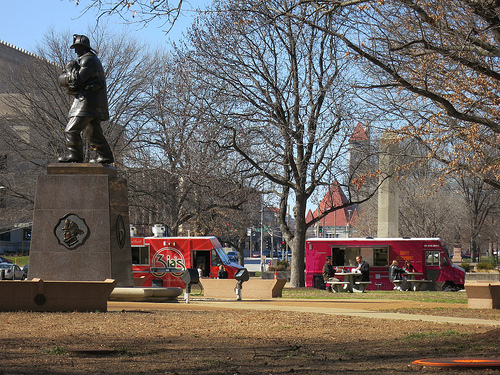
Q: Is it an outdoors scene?
A: Yes, it is outdoors.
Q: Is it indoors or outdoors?
A: It is outdoors.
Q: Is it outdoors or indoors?
A: It is outdoors.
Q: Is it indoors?
A: No, it is outdoors.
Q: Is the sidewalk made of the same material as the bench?
A: Yes, both the sidewalk and the bench are made of cement.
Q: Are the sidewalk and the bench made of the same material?
A: Yes, both the sidewalk and the bench are made of cement.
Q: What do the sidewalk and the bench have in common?
A: The material, both the sidewalk and the bench are concrete.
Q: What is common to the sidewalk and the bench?
A: The material, both the sidewalk and the bench are concrete.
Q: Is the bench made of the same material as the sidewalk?
A: Yes, both the bench and the sidewalk are made of cement.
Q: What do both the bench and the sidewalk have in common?
A: The material, both the bench and the sidewalk are concrete.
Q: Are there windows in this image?
A: Yes, there is a window.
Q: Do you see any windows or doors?
A: Yes, there is a window.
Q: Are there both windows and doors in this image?
A: No, there is a window but no doors.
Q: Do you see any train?
A: No, there are no trains.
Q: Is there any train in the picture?
A: No, there are no trains.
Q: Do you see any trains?
A: No, there are no trains.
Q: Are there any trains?
A: No, there are no trains.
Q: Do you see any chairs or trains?
A: No, there are no trains or chairs.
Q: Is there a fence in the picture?
A: No, there are no fences.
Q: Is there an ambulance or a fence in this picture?
A: No, there are no fences or ambulances.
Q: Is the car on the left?
A: Yes, the car is on the left of the image.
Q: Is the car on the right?
A: No, the car is on the left of the image.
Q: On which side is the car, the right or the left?
A: The car is on the left of the image.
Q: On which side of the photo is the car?
A: The car is on the left of the image.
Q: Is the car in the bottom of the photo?
A: Yes, the car is in the bottom of the image.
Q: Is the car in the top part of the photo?
A: No, the car is in the bottom of the image.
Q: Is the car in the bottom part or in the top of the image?
A: The car is in the bottom of the image.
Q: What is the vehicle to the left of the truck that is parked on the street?
A: The vehicle is a car.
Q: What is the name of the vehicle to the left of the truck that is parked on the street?
A: The vehicle is a car.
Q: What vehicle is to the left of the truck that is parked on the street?
A: The vehicle is a car.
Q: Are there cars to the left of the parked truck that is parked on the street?
A: Yes, there is a car to the left of the truck.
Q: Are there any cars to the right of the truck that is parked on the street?
A: No, the car is to the left of the truck.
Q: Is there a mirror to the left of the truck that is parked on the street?
A: No, there is a car to the left of the truck.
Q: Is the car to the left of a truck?
A: Yes, the car is to the left of a truck.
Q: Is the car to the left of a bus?
A: No, the car is to the left of a truck.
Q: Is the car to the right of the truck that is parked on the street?
A: No, the car is to the left of the truck.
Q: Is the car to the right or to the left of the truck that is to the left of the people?
A: The car is to the left of the truck.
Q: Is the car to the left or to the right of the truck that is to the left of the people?
A: The car is to the left of the truck.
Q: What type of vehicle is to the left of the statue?
A: The vehicle is a car.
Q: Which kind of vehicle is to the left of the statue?
A: The vehicle is a car.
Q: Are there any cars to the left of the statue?
A: Yes, there is a car to the left of the statue.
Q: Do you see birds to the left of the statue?
A: No, there is a car to the left of the statue.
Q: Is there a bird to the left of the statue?
A: No, there is a car to the left of the statue.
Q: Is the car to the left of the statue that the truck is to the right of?
A: Yes, the car is to the left of the statue.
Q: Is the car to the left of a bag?
A: No, the car is to the left of the statue.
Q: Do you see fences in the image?
A: No, there are no fences.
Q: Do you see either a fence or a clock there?
A: No, there are no fences or clocks.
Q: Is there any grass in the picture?
A: Yes, there is grass.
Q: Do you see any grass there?
A: Yes, there is grass.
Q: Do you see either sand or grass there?
A: Yes, there is grass.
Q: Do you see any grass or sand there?
A: Yes, there is grass.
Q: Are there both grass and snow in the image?
A: No, there is grass but no snow.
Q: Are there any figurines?
A: No, there are no figurines.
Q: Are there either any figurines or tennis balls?
A: No, there are no figurines or tennis balls.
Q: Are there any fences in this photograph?
A: No, there are no fences.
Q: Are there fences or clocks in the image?
A: No, there are no fences or clocks.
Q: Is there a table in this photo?
A: Yes, there is a table.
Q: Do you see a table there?
A: Yes, there is a table.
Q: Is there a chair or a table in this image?
A: Yes, there is a table.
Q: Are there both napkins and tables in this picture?
A: No, there is a table but no napkins.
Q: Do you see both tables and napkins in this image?
A: No, there is a table but no napkins.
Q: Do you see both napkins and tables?
A: No, there is a table but no napkins.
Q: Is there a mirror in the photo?
A: No, there are no mirrors.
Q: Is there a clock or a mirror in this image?
A: No, there are no mirrors or clocks.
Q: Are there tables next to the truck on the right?
A: Yes, there is a table next to the truck.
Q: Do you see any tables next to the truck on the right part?
A: Yes, there is a table next to the truck.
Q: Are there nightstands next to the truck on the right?
A: No, there is a table next to the truck.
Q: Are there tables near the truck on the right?
A: Yes, there is a table near the truck.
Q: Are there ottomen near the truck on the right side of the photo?
A: No, there is a table near the truck.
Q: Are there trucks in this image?
A: Yes, there is a truck.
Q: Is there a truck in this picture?
A: Yes, there is a truck.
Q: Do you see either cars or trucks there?
A: Yes, there is a truck.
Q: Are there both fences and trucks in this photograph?
A: No, there is a truck but no fences.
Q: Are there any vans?
A: No, there are no vans.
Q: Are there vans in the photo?
A: No, there are no vans.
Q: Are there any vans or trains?
A: No, there are no vans or trains.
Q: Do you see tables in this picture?
A: Yes, there is a table.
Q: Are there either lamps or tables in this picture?
A: Yes, there is a table.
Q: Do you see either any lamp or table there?
A: Yes, there is a table.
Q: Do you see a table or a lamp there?
A: Yes, there is a table.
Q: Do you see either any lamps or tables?
A: Yes, there is a table.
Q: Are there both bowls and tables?
A: No, there is a table but no bowls.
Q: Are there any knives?
A: No, there are no knives.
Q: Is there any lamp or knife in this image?
A: No, there are no knives or lamps.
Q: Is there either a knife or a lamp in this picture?
A: No, there are no knives or lamps.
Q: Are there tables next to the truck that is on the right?
A: Yes, there is a table next to the truck.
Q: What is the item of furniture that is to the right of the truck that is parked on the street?
A: The piece of furniture is a table.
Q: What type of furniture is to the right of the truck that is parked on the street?
A: The piece of furniture is a table.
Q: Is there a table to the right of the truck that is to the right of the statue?
A: Yes, there is a table to the right of the truck.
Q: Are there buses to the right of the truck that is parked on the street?
A: No, there is a table to the right of the truck.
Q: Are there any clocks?
A: No, there are no clocks.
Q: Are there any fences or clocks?
A: No, there are no clocks or fences.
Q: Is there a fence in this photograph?
A: No, there are no fences.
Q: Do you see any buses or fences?
A: No, there are no fences or buses.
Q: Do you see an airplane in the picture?
A: No, there are no airplanes.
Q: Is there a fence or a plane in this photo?
A: No, there are no airplanes or fences.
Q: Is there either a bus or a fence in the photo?
A: No, there are no fences or buses.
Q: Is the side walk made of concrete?
A: Yes, the side walk is made of concrete.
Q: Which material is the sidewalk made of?
A: The sidewalk is made of cement.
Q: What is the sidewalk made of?
A: The sidewalk is made of concrete.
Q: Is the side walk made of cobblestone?
A: No, the side walk is made of concrete.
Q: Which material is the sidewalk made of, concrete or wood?
A: The sidewalk is made of concrete.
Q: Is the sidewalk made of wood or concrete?
A: The sidewalk is made of concrete.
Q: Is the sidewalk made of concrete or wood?
A: The sidewalk is made of concrete.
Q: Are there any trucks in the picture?
A: Yes, there is a truck.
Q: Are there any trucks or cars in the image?
A: Yes, there is a truck.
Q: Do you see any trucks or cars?
A: Yes, there is a truck.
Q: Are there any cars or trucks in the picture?
A: Yes, there is a truck.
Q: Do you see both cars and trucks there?
A: Yes, there are both a truck and a car.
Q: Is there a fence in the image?
A: No, there are no fences.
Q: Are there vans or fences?
A: No, there are no fences or vans.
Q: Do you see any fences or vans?
A: No, there are no fences or vans.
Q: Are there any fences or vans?
A: No, there are no fences or vans.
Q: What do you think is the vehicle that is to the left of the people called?
A: The vehicle is a truck.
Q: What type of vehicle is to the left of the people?
A: The vehicle is a truck.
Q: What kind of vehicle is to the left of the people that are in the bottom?
A: The vehicle is a truck.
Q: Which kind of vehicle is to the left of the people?
A: The vehicle is a truck.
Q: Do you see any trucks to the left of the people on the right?
A: Yes, there is a truck to the left of the people.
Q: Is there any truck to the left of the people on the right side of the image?
A: Yes, there is a truck to the left of the people.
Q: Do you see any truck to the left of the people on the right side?
A: Yes, there is a truck to the left of the people.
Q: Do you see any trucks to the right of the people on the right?
A: No, the truck is to the left of the people.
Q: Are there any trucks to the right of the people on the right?
A: No, the truck is to the left of the people.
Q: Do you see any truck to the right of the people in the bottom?
A: No, the truck is to the left of the people.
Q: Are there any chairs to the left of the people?
A: No, there is a truck to the left of the people.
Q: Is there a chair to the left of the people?
A: No, there is a truck to the left of the people.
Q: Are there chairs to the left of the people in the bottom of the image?
A: No, there is a truck to the left of the people.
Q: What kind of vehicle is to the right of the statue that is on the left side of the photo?
A: The vehicle is a truck.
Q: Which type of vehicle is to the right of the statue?
A: The vehicle is a truck.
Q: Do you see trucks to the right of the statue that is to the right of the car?
A: Yes, there is a truck to the right of the statue.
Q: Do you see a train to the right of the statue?
A: No, there is a truck to the right of the statue.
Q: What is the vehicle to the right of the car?
A: The vehicle is a truck.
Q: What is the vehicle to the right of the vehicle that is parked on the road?
A: The vehicle is a truck.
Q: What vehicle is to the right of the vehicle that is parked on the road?
A: The vehicle is a truck.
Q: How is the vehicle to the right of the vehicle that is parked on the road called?
A: The vehicle is a truck.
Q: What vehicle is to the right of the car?
A: The vehicle is a truck.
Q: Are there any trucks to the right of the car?
A: Yes, there is a truck to the right of the car.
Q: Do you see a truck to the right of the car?
A: Yes, there is a truck to the right of the car.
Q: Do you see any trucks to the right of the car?
A: Yes, there is a truck to the right of the car.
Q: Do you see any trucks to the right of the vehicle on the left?
A: Yes, there is a truck to the right of the car.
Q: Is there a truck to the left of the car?
A: No, the truck is to the right of the car.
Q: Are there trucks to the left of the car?
A: No, the truck is to the right of the car.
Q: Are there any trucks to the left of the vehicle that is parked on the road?
A: No, the truck is to the right of the car.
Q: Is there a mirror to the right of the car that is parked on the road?
A: No, there is a truck to the right of the car.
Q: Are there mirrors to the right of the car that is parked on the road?
A: No, there is a truck to the right of the car.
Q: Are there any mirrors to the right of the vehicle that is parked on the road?
A: No, there is a truck to the right of the car.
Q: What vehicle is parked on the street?
A: The vehicle is a truck.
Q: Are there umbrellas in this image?
A: No, there are no umbrellas.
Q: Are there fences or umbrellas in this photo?
A: No, there are no umbrellas or fences.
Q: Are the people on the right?
A: Yes, the people are on the right of the image.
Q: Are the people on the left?
A: No, the people are on the right of the image.